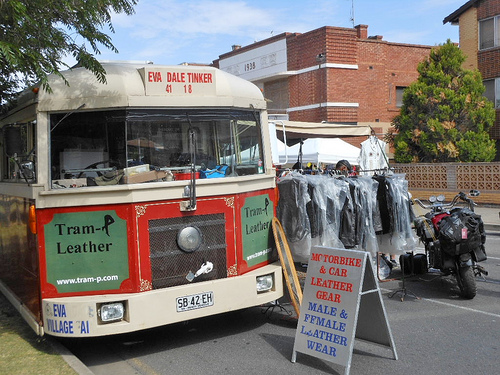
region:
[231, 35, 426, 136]
A red brick building.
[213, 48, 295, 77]
White square sign on the front of the building.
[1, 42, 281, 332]
An older bus this mostly white.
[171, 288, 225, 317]
License tag on bumper of bus.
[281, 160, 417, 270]
A rack of clothing.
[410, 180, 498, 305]
An older motorcycle.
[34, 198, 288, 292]
A front section of the bus is red.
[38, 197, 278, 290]
Two advertisements for tram leather.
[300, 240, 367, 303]
A sign advertising MOTORBIKE & CAR LEATHER GEAR.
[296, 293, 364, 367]
A sign advertising MALE & FEMALE LEATHER WEAR.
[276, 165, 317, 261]
clothes in the plastic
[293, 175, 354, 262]
clothes in the plastic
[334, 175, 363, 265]
clothes in the plastic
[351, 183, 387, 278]
clothes in the plastic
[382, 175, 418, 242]
clothes in the plastic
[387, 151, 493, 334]
the motorbike is parked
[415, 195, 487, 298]
a motorcycle parked in the street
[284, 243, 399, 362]
a white sign on the street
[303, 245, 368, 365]
a white sign with red and blue lettering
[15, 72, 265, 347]
a bus on the side of the road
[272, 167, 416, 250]
a rack of clothes on the street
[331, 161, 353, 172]
a man's head peaking above the rack of clothes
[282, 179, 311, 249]
plastic bags wrapped around clothes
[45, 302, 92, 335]
blue lettering on the bus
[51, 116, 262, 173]
a bus's front window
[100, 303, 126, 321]
the right headlight of a bus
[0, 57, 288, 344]
off white and red bus parked on a street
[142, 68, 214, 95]
red text on the front of a bus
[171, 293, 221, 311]
white and black bus license plate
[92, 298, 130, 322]
square white light on the front of bus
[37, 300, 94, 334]
blue print on the front of a bus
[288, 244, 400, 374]
gray sign on a street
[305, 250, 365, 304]
red print on a gray sign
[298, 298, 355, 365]
blue text on a gray sign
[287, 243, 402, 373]
red and blue text on a gray sign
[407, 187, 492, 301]
motorcycle parked on a street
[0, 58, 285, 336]
portable leather clothing store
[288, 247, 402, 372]
sign to inform people passing by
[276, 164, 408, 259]
leather clothing wrack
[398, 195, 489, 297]
antique motorcyle to draw in customers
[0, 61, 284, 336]
very old bus turned into store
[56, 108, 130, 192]
driver seat is on right hand side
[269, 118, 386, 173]
other vendor tents set up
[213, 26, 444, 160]
large brick building across road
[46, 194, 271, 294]
large signs on bus tell people the name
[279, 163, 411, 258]
all leather clothes are in plastic protective bags